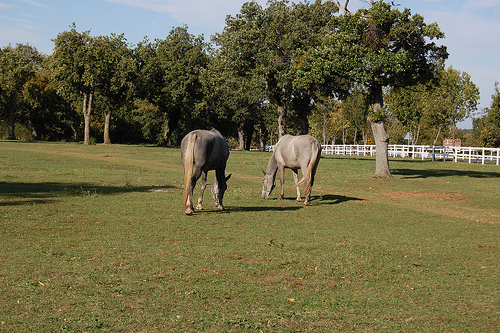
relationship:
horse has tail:
[257, 134, 323, 204] [306, 138, 321, 190]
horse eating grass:
[257, 134, 323, 204] [3, 144, 94, 218]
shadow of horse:
[2, 168, 178, 209] [257, 134, 323, 204]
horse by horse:
[257, 134, 323, 204] [177, 124, 233, 219]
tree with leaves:
[51, 22, 117, 144] [89, 51, 101, 61]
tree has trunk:
[51, 22, 117, 144] [81, 94, 92, 144]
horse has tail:
[177, 124, 233, 219] [182, 133, 198, 209]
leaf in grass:
[283, 293, 299, 306] [3, 144, 94, 218]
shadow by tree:
[2, 168, 178, 209] [51, 22, 117, 144]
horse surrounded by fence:
[257, 134, 323, 204] [392, 140, 499, 164]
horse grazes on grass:
[257, 134, 323, 204] [3, 144, 94, 218]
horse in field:
[257, 134, 323, 204] [2, 139, 499, 332]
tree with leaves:
[216, 5, 337, 161] [268, 24, 289, 41]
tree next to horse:
[292, 2, 450, 190] [257, 134, 323, 204]